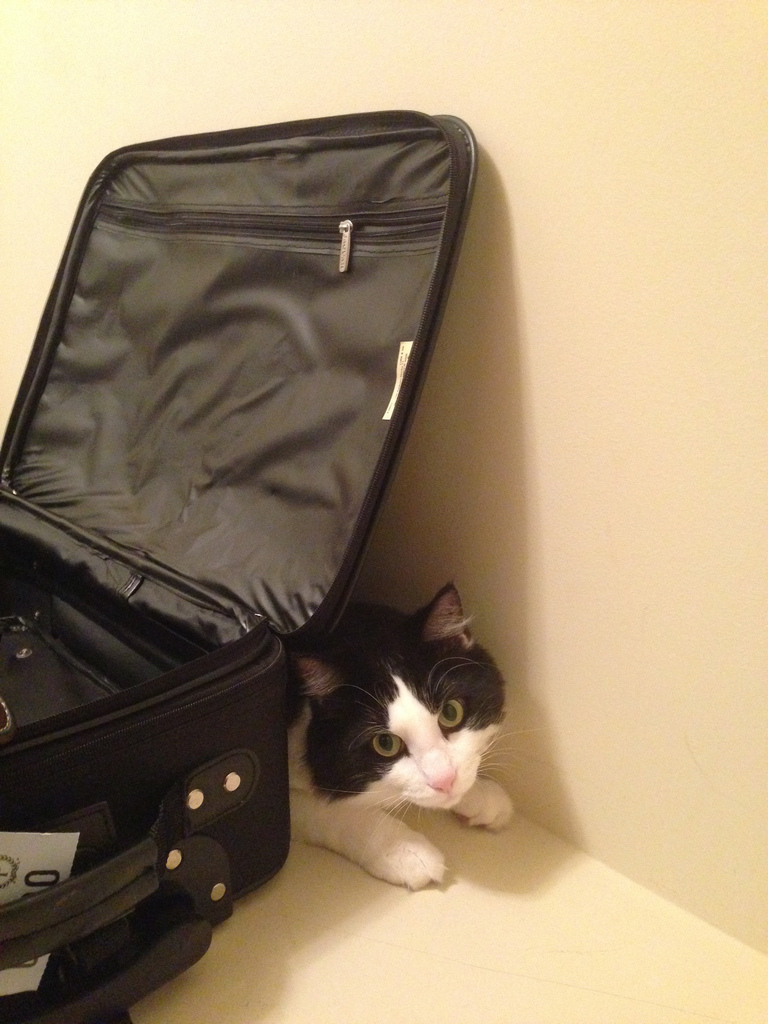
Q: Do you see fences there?
A: No, there are no fences.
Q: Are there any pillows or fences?
A: No, there are no fences or pillows.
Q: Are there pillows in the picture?
A: No, there are no pillows.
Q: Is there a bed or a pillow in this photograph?
A: No, there are no pillows or beds.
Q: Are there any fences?
A: No, there are no fences.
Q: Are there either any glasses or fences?
A: No, there are no fences or glasses.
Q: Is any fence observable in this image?
A: No, there are no fences.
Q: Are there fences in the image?
A: No, there are no fences.